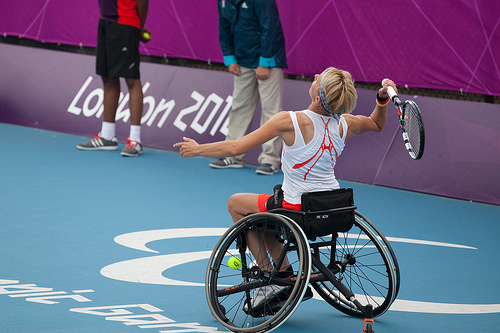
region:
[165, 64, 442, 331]
Blonde woman playing tennis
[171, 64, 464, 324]
Woman holding tennis racket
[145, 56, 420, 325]
Woman in sports wheelchair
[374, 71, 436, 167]
Black and white tennis racket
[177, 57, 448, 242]
Woman wearing white tank top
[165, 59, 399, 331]
Woman wearing red shorts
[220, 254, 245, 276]
Bright green tennis ball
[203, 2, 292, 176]
Man in khaki pants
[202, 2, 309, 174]
Man in teal jacket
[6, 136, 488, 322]
Blue tennis court floor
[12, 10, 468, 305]
disabled tennis player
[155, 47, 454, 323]
female tennis player in a wheelchair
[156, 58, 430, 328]
female disabled tennis player wearing a tank top shorts and a headband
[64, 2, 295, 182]
ball runner and umpire in the background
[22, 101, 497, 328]
flooring is blue with white lettering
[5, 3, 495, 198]
background is purple and lavendar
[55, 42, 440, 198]
background wall has London 2010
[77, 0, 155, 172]
ball runner is wearing black shorts and a red and black shirt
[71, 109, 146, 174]
ball runner has grey and white Adidas sneakers that have red shoelaces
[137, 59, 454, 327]
female disabled tennis player preparing to hit a ball with her racket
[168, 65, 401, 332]
woman sitting in wheelchair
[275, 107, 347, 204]
woman wearing white tank top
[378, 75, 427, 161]
woman holding tennis racket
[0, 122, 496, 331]
tennis court blue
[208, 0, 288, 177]
man standing near purple wall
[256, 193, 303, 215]
woman wearing red shorts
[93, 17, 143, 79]
man wearing black shorts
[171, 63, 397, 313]
woman preparing to hit ball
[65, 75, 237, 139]
purple wall has white writing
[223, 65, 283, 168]
man wearing tan pants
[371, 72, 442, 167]
a tennis racket in a hand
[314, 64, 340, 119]
a blue headband on a head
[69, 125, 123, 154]
a tennis shoe with three white stripes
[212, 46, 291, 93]
two hands in front of a person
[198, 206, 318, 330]
one wheel of a wheelchair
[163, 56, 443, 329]
a wheelchair bound tennis player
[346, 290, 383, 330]
a balancing wheel on the rear of a wheelchair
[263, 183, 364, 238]
the seat on a wheelchair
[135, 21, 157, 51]
a yellow tennis ball in a persons hand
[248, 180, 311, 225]
red shorts on a wheelchair bound player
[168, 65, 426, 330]
tennis player in wheelchair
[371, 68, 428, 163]
tennis player holding racket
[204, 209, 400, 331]
wheelchair wheels slant inward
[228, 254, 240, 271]
yellow tennic ball on ground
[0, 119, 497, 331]
ground is blue with white letters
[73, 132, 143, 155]
man wearing black tennis shoes with white stripes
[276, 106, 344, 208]
tennis player wearing white tank top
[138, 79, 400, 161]
tennis player has muscular arms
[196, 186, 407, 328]
wheelchair is black and has no handles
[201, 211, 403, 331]
wheels have many spokes